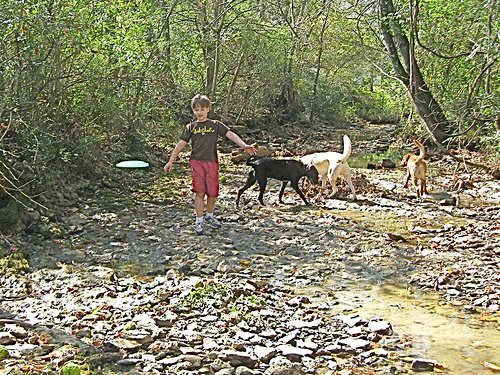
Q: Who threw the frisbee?
A: The boy.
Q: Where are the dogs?
A: Behind boy.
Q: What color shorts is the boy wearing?
A: Red.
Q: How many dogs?
A: Three.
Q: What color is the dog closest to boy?
A: Black.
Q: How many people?
A: One.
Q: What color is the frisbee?
A: Green.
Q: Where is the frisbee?
A: In air.